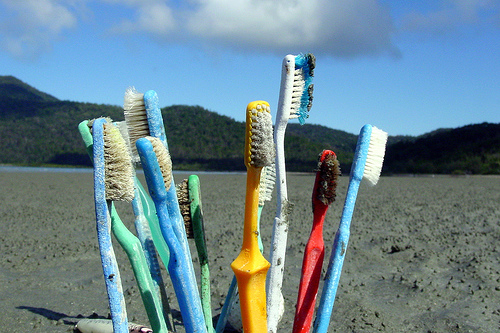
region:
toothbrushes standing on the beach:
[9, 8, 498, 298]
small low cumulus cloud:
[124, 3, 446, 67]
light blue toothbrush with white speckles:
[87, 108, 143, 332]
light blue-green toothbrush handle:
[109, 204, 171, 331]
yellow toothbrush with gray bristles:
[224, 94, 277, 331]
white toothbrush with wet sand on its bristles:
[266, 46, 313, 327]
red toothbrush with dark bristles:
[298, 140, 337, 332]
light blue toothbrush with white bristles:
[327, 121, 397, 332]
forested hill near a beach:
[4, 61, 87, 161]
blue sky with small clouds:
[321, 13, 493, 112]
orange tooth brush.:
[200, 86, 280, 331]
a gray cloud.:
[130, 0, 420, 70]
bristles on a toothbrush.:
[235, 75, 280, 185]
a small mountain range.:
[0, 50, 495, 175]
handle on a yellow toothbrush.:
[215, 196, 270, 326]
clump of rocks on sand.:
[358, 228, 428, 300]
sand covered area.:
[0, 165, 492, 330]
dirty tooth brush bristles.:
[301, 150, 341, 240]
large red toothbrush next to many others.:
[281, 138, 352, 330]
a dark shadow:
[28, 281, 88, 327]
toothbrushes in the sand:
[61, 46, 393, 331]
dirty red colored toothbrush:
[297, 139, 334, 331]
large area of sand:
[1, 162, 499, 330]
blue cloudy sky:
[1, 0, 495, 142]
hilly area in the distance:
[0, 72, 499, 182]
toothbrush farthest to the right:
[316, 117, 396, 330]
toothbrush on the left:
[86, 118, 153, 327]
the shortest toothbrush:
[173, 170, 225, 331]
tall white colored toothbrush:
[268, 47, 318, 332]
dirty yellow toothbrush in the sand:
[229, 88, 276, 328]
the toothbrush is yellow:
[213, 91, 307, 323]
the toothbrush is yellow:
[250, 64, 317, 331]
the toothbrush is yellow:
[241, 76, 273, 305]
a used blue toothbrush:
[92, 116, 139, 331]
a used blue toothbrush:
[137, 136, 210, 331]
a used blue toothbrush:
[123, 83, 168, 164]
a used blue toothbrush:
[308, 122, 397, 330]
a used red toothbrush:
[289, 148, 339, 328]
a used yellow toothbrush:
[233, 94, 273, 330]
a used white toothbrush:
[271, 49, 316, 329]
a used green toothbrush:
[173, 171, 216, 330]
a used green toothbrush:
[76, 116, 163, 331]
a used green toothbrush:
[113, 119, 171, 273]